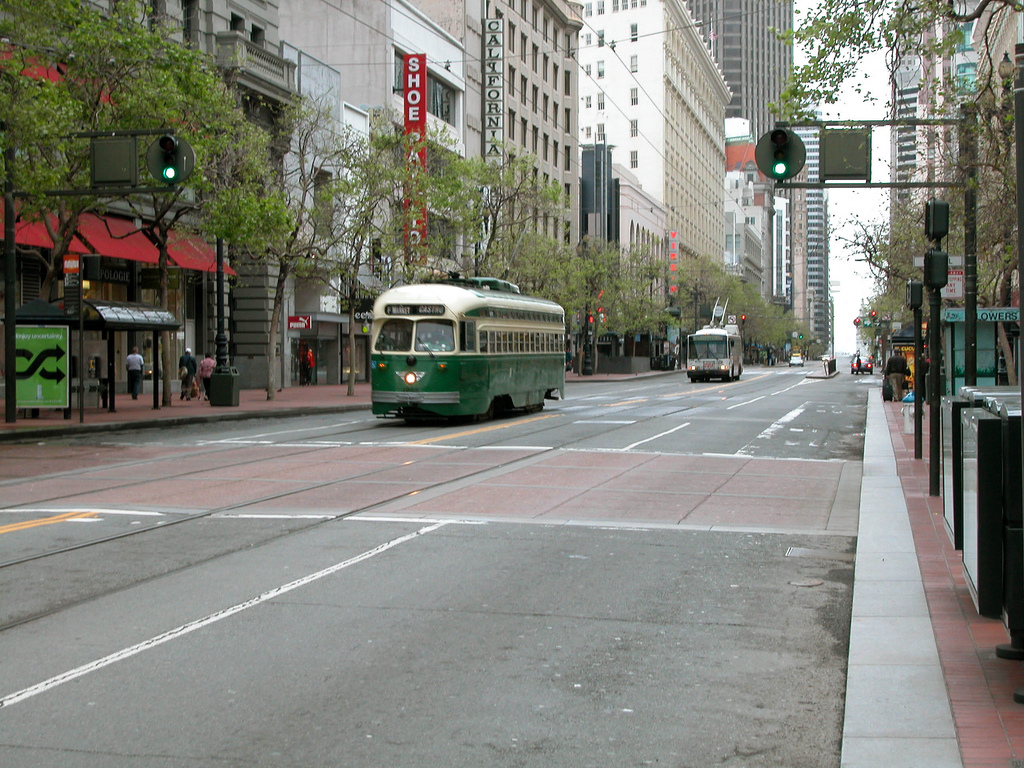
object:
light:
[165, 165, 176, 178]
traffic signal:
[145, 135, 194, 183]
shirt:
[124, 354, 143, 371]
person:
[124, 346, 144, 400]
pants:
[128, 369, 142, 397]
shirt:
[180, 354, 199, 376]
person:
[178, 347, 198, 401]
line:
[2, 508, 489, 710]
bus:
[682, 297, 743, 384]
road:
[2, 357, 868, 763]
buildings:
[2, 1, 835, 394]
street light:
[774, 162, 787, 175]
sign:
[403, 53, 428, 264]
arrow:
[16, 343, 66, 384]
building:
[406, 0, 586, 367]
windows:
[496, 0, 570, 245]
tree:
[2, 0, 300, 406]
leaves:
[0, 0, 296, 256]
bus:
[370, 219, 567, 425]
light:
[403, 372, 416, 385]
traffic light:
[755, 128, 807, 180]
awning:
[0, 197, 238, 276]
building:
[0, 1, 484, 394]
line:
[2, 510, 100, 532]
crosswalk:
[0, 444, 862, 539]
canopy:
[83, 298, 182, 326]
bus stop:
[83, 299, 182, 412]